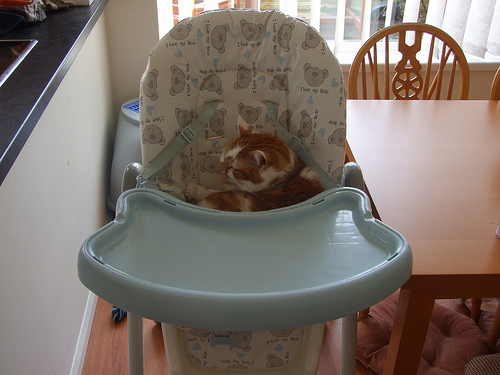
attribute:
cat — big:
[154, 113, 323, 212]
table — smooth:
[351, 86, 498, 278]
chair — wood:
[346, 22, 476, 99]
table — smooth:
[337, 92, 498, 371]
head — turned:
[210, 111, 303, 195]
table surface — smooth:
[347, 101, 497, 283]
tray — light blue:
[109, 190, 397, 323]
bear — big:
[181, 127, 326, 210]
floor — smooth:
[82, 287, 169, 374]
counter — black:
[2, 0, 109, 187]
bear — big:
[221, 125, 297, 211]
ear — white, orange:
[234, 115, 251, 137]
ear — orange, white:
[252, 147, 267, 168]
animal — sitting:
[118, 91, 358, 249]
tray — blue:
[80, 180, 412, 326]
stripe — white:
[218, 147, 285, 189]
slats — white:
[157, 56, 199, 86]